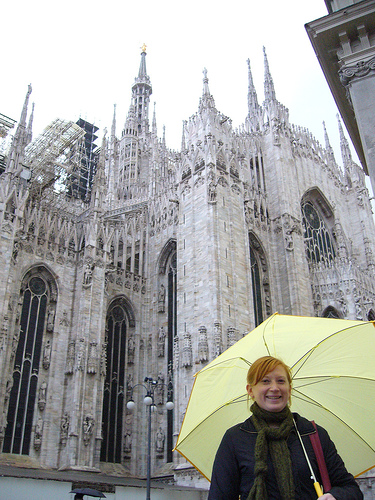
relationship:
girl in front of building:
[206, 353, 367, 500] [0, 44, 374, 499]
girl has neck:
[206, 353, 367, 500] [251, 403, 293, 431]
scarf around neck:
[248, 403, 298, 499] [251, 403, 293, 431]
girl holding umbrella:
[206, 353, 367, 500] [188, 295, 374, 427]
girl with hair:
[206, 353, 367, 500] [248, 358, 295, 394]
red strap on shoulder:
[307, 419, 337, 492] [295, 413, 331, 434]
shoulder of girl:
[295, 413, 331, 434] [206, 353, 367, 500]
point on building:
[200, 68, 215, 109] [2, 42, 374, 498]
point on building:
[246, 55, 258, 110] [2, 42, 374, 498]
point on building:
[133, 41, 149, 132] [2, 42, 374, 498]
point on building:
[151, 100, 157, 131] [2, 42, 374, 498]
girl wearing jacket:
[206, 353, 367, 500] [206, 415, 362, 498]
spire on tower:
[135, 44, 150, 75] [258, 41, 283, 119]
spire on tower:
[244, 61, 256, 93] [244, 56, 257, 110]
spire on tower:
[133, 42, 149, 82] [116, 40, 173, 157]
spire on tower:
[135, 44, 150, 75] [119, 38, 169, 125]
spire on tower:
[110, 106, 118, 147] [121, 39, 157, 194]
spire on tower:
[20, 80, 32, 128] [181, 63, 236, 185]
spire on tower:
[316, 118, 341, 162] [241, 39, 292, 127]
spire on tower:
[334, 112, 355, 177] [12, 80, 39, 183]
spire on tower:
[21, 77, 39, 115] [11, 37, 365, 314]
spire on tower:
[130, 39, 151, 76] [11, 37, 365, 314]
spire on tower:
[197, 67, 215, 98] [11, 37, 365, 314]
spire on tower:
[244, 61, 256, 93] [11, 37, 365, 314]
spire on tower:
[255, 41, 275, 77] [11, 37, 365, 314]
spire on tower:
[316, 118, 341, 162] [11, 37, 365, 314]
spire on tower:
[100, 83, 127, 155] [96, 50, 191, 215]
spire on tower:
[135, 44, 150, 75] [18, 38, 359, 466]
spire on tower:
[334, 112, 355, 177] [175, 50, 257, 330]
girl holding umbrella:
[206, 353, 367, 500] [171, 310, 373, 479]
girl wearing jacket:
[206, 353, 367, 500] [221, 425, 362, 472]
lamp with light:
[126, 375, 174, 413] [144, 396, 157, 405]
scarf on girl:
[247, 403, 298, 498] [206, 353, 367, 500]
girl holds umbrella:
[206, 353, 367, 500] [171, 310, 373, 479]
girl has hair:
[206, 353, 366, 497] [249, 356, 275, 373]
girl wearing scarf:
[206, 353, 367, 500] [247, 403, 298, 498]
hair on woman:
[246, 356, 293, 410] [204, 346, 370, 496]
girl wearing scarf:
[206, 353, 366, 497] [238, 398, 300, 497]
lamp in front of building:
[122, 381, 173, 415] [0, 44, 374, 499]